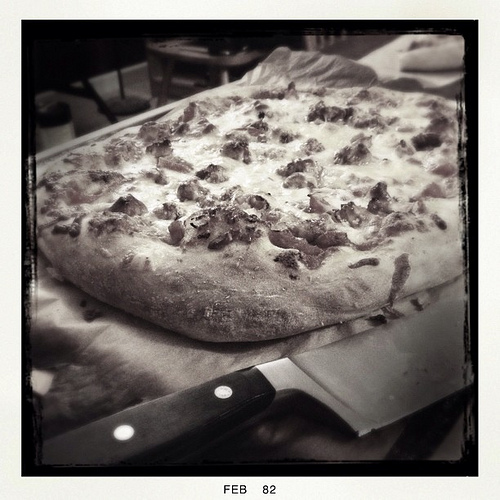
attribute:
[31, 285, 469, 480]
knife — silver, utensil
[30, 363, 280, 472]
handle — wood, black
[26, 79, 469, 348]
pizza — ready, thick, sliced, baked, crusty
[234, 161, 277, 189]
cheese — melted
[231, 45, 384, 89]
paper — brown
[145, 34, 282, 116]
chair — behind